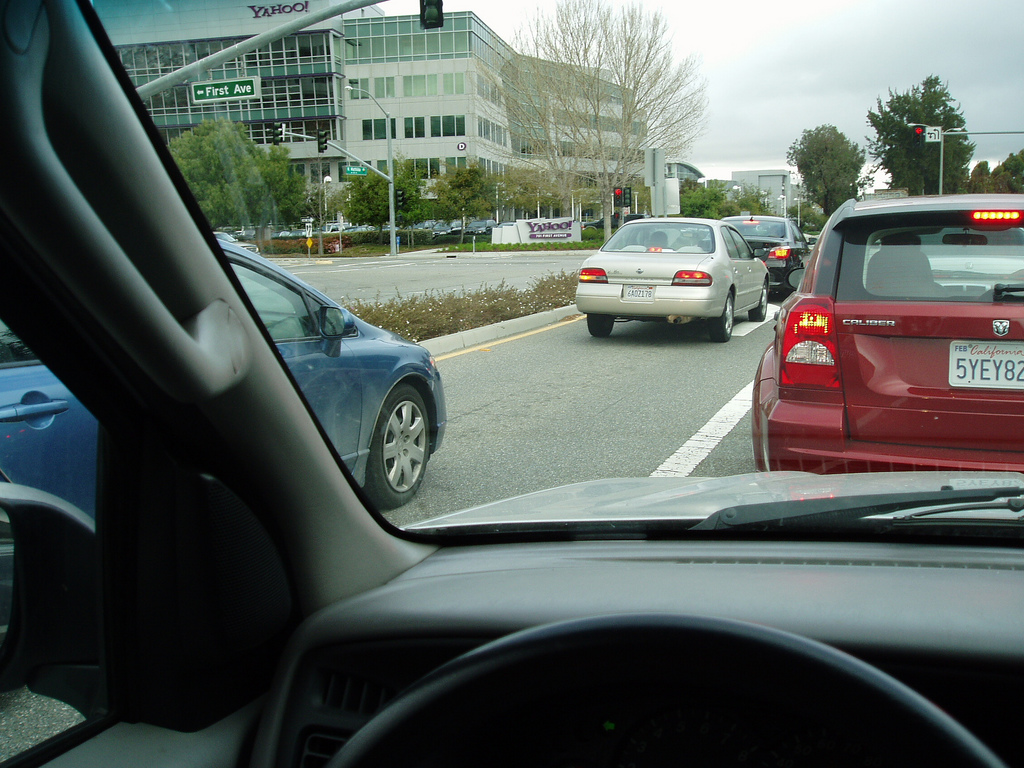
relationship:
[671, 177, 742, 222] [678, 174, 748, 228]
leaves on tree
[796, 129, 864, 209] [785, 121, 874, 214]
leaves on tree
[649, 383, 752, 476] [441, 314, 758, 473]
line drawn on street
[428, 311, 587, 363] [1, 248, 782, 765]
line drawn on street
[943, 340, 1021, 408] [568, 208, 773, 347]
license plate on car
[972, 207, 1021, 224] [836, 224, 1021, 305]
mini lights at top of windshield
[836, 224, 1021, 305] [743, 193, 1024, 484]
windshield on cars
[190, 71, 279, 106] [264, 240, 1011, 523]
street sign above street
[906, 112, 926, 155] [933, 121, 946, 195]
light hanging from pole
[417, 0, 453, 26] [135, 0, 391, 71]
light hanging from pole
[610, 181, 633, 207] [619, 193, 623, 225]
light hanging from pole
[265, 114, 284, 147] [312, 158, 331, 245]
light hanging from pole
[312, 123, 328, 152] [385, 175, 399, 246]
light hanging from pole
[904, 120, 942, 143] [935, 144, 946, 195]
traffic sign on pole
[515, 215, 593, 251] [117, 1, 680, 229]
sign in front of building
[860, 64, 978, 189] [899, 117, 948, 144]
tree behind street light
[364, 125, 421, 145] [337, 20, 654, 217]
window on building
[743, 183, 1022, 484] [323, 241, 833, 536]
car on street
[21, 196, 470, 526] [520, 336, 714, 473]
car on street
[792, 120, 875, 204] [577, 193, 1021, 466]
tree in front of cars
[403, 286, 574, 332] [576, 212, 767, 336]
weeds next to car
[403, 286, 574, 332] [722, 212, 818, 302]
weeds next to car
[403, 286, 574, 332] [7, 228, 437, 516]
weeds next to car